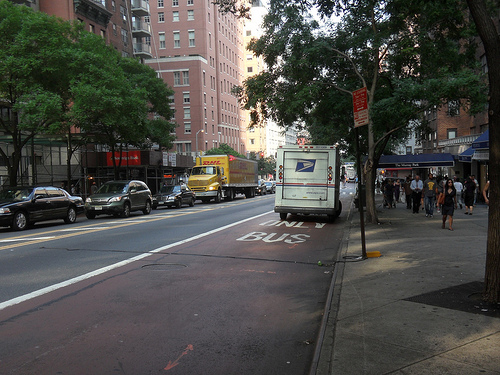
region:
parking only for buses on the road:
[183, 213, 368, 342]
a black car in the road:
[1, 176, 87, 241]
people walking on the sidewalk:
[362, 140, 487, 248]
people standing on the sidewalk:
[371, 160, 463, 231]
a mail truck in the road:
[249, 129, 366, 244]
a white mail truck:
[251, 133, 363, 223]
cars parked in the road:
[18, 157, 282, 234]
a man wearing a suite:
[396, 163, 427, 214]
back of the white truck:
[276, 143, 336, 208]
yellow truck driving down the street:
[186, 153, 256, 200]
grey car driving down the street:
[85, 178, 151, 218]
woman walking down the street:
[440, 176, 456, 228]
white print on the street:
[233, 217, 324, 244]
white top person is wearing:
[450, 180, 461, 191]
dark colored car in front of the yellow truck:
[155, 182, 195, 207]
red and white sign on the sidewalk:
[350, 87, 367, 127]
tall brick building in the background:
[150, 1, 243, 153]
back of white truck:
[274, 148, 341, 216]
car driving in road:
[0, 187, 83, 229]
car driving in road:
[87, 178, 155, 220]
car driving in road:
[154, 175, 194, 211]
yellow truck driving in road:
[182, 153, 259, 204]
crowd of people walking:
[374, 180, 485, 225]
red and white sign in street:
[350, 86, 374, 130]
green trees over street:
[3, 0, 175, 150]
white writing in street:
[240, 219, 325, 246]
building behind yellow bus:
[136, 0, 267, 156]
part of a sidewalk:
[341, 197, 496, 372]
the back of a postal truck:
[270, 141, 335, 211]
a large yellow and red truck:
[180, 155, 255, 200]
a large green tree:
[0, 0, 125, 170]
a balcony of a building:
[130, 16, 153, 36]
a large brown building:
[145, 2, 246, 154]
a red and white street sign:
[350, 85, 369, 126]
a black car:
[2, 181, 89, 231]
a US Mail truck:
[273, 143, 340, 218]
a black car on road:
[0, 182, 85, 229]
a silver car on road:
[84, 177, 151, 220]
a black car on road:
[154, 182, 196, 209]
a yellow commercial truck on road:
[186, 153, 258, 200]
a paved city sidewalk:
[325, 182, 498, 373]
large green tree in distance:
[2, 3, 174, 189]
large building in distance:
[147, 2, 264, 166]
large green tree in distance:
[224, 2, 481, 211]